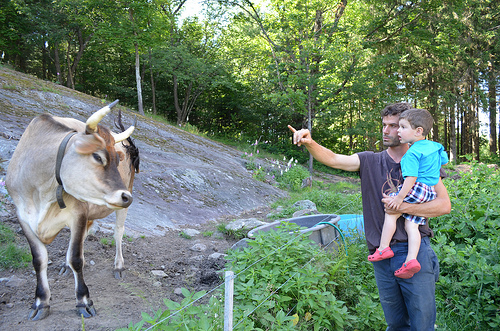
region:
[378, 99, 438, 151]
father and son looking at cow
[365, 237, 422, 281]
pink shoes worn by child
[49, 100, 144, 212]
cow looking at the people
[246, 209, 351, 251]
where cow can drink water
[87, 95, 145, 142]
horns with gray tips on cow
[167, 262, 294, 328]
part of fence keeps cow enclosed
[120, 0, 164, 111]
tree growing on side of hill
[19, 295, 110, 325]
front hooves of the cow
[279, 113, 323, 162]
man's hand as he points at cow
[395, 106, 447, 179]
child wearing bright blue shirt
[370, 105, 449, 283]
young boy in blue shirt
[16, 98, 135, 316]
bull with sharp horns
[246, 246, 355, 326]
green weeds growing on mountain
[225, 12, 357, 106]
green leaves on tall trees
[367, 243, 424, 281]
pair of red shoes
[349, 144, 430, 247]
short sleeve black shirt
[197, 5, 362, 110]
sun shining on tree tops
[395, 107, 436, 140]
short brown hair on boy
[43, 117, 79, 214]
collar on bull's neck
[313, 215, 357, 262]
green garden hose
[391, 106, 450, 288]
a small boy with blue shirt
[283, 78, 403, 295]
a man with grey t shirt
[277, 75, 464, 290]
a man with small boy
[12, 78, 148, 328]
a cow in the field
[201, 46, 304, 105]
the green trees in the park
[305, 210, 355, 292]
the green color pipe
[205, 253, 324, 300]
the wiring to protect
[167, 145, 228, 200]
the rock in the park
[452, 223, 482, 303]
the studs in the park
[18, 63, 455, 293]
a man showing a cow in the park to his son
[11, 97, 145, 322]
a gray and black bull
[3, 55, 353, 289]
a rocky hill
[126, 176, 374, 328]
a wire fence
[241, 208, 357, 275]
a gray plastic tub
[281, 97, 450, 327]
a man extending his pinky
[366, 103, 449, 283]
a toddler in a blue shirt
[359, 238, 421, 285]
a pair of small red Crocs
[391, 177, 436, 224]
plaid shorts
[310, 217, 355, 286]
a green water hose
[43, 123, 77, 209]
a black collar around the bull's neck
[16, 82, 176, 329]
a brown cow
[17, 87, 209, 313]
a brown cow with horns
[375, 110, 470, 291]
a small boy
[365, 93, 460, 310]
a small boy wearing red shoes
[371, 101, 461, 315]
a small boy wearing plaid shorts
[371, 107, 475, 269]
a small boy wearing a blue tshirt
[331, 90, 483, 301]
a man wearing a grey shirt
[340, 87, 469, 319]
a man wearing blue jeans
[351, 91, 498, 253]
a man holding a small boy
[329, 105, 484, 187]
a man with brown hair